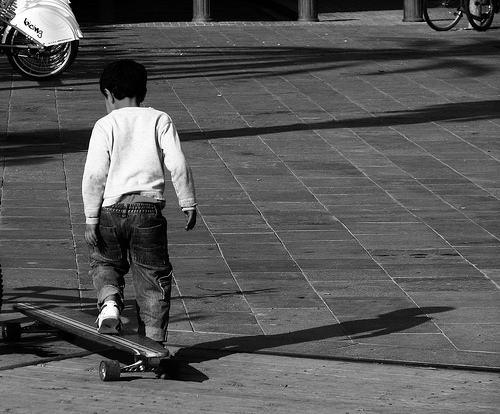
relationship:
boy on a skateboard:
[59, 66, 266, 374] [8, 288, 170, 380]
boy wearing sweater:
[59, 66, 266, 374] [60, 94, 218, 226]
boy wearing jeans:
[59, 66, 266, 374] [89, 195, 171, 340]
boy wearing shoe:
[59, 66, 266, 374] [95, 300, 120, 333]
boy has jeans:
[59, 66, 266, 374] [80, 195, 175, 340]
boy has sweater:
[59, 66, 266, 374] [94, 104, 208, 211]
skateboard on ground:
[23, 292, 93, 340] [190, 235, 493, 365]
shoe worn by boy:
[95, 300, 122, 334] [59, 66, 266, 374]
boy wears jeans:
[59, 66, 266, 374] [87, 207, 175, 351]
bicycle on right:
[415, 4, 495, 39] [414, 13, 498, 411]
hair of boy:
[95, 63, 149, 100] [59, 66, 266, 374]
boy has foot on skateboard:
[59, 66, 266, 374] [8, 296, 168, 378]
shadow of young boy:
[158, 299, 455, 385] [68, 56, 203, 370]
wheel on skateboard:
[99, 358, 121, 381] [6, 291, 169, 362]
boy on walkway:
[59, 66, 266, 374] [1, 342, 496, 409]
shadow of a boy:
[158, 299, 455, 385] [59, 66, 266, 374]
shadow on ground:
[179, 299, 453, 379] [67, 88, 472, 392]